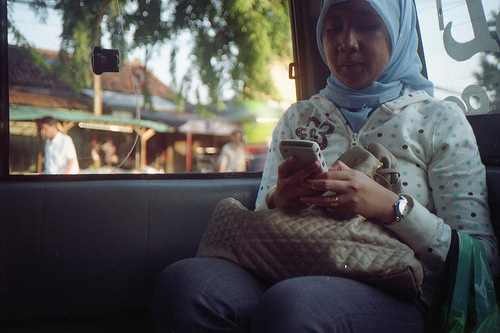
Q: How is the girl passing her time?
A: Looking at her phone.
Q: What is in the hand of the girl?
A: A cell phone.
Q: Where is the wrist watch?
A: Left wrist.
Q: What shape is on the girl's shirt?
A: Circles or dots.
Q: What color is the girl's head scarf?
A: Blue.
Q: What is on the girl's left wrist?
A: A wrist watch.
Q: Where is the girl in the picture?
A: Inside a vehicle.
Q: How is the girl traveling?
A: By vehicle.